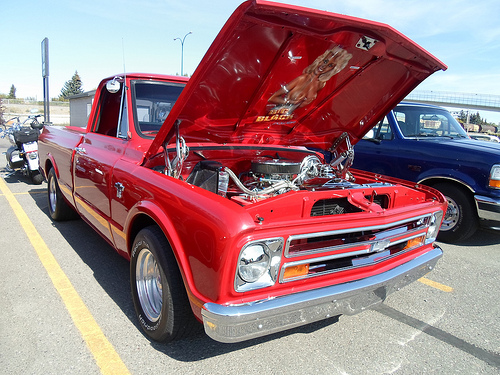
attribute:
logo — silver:
[367, 236, 391, 255]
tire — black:
[121, 219, 197, 342]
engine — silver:
[200, 140, 380, 213]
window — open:
[86, 83, 128, 140]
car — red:
[37, 7, 446, 348]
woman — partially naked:
[263, 38, 355, 124]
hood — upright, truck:
[145, 4, 448, 168]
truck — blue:
[351, 100, 498, 251]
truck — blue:
[348, 97, 498, 241]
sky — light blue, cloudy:
[2, 5, 498, 116]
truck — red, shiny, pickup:
[37, 2, 459, 358]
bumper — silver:
[187, 239, 442, 350]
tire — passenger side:
[119, 219, 200, 358]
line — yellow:
[2, 184, 132, 373]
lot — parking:
[1, 144, 498, 372]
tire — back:
[40, 163, 80, 224]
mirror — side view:
[103, 70, 123, 96]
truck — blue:
[342, 92, 498, 249]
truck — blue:
[34, 38, 453, 349]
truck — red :
[50, 42, 446, 330]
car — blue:
[382, 86, 452, 237]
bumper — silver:
[177, 203, 418, 367]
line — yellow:
[0, 201, 131, 370]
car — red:
[27, 4, 451, 325]